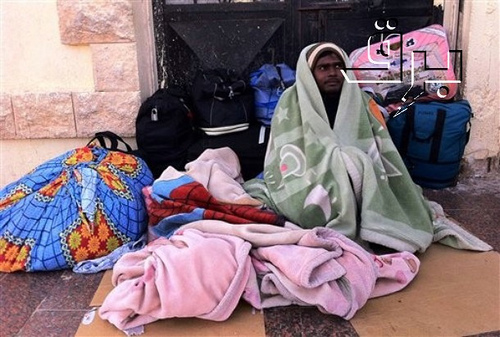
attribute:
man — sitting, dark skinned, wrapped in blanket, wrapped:
[262, 40, 431, 257]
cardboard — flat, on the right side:
[321, 210, 483, 336]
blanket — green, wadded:
[241, 41, 496, 262]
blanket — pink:
[99, 217, 420, 335]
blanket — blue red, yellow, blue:
[2, 144, 153, 275]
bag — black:
[133, 88, 193, 160]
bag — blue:
[249, 62, 297, 126]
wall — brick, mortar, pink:
[1, 0, 152, 187]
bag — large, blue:
[383, 97, 476, 196]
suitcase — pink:
[348, 21, 461, 114]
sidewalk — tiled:
[2, 187, 496, 335]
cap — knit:
[304, 44, 349, 72]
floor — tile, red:
[2, 260, 104, 336]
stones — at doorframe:
[57, 5, 141, 143]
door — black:
[156, 3, 446, 93]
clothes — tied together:
[72, 237, 148, 276]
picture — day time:
[1, 5, 495, 335]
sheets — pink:
[158, 148, 259, 207]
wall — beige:
[454, 3, 499, 160]